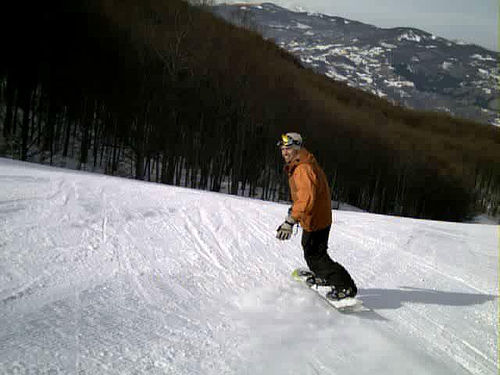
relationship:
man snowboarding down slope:
[274, 132, 356, 302] [68, 212, 245, 360]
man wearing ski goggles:
[274, 132, 356, 302] [275, 133, 302, 147]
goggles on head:
[275, 133, 302, 147] [274, 127, 305, 164]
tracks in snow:
[175, 267, 292, 329] [29, 177, 474, 364]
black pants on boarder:
[301, 223, 356, 292] [271, 128, 360, 302]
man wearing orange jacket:
[274, 132, 356, 302] [278, 149, 335, 234]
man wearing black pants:
[274, 132, 356, 302] [302, 221, 356, 291]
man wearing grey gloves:
[274, 132, 356, 302] [271, 211, 301, 245]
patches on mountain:
[0, 156, 465, 372] [9, 2, 490, 222]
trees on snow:
[0, 0, 484, 234] [2, 151, 484, 371]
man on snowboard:
[274, 132, 356, 302] [284, 261, 367, 317]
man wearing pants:
[241, 117, 386, 311] [276, 214, 367, 291]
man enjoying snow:
[274, 132, 356, 302] [2, 151, 484, 371]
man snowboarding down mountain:
[274, 132, 356, 302] [4, 4, 467, 369]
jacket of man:
[283, 146, 333, 233] [274, 132, 356, 302]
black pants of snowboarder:
[293, 200, 355, 305] [271, 125, 363, 315]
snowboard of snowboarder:
[298, 245, 382, 327] [269, 122, 359, 306]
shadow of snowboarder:
[351, 278, 484, 321] [264, 120, 371, 316]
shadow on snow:
[351, 278, 484, 321] [76, 239, 240, 326]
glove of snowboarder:
[275, 206, 294, 240] [261, 124, 377, 356]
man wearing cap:
[274, 132, 356, 302] [275, 130, 301, 149]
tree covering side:
[165, 55, 191, 182] [2, 1, 483, 220]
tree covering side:
[265, 68, 286, 195] [2, 1, 483, 220]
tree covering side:
[95, 34, 122, 168] [2, 1, 483, 220]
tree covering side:
[22, 18, 52, 150] [2, 1, 483, 220]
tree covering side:
[3, 1, 28, 159] [2, 1, 483, 220]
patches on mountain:
[275, 4, 445, 118] [204, 0, 484, 142]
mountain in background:
[204, 0, 484, 142] [164, 3, 482, 137]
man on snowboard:
[274, 132, 356, 302] [293, 265, 361, 317]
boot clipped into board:
[296, 267, 388, 312] [287, 257, 366, 316]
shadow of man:
[351, 285, 499, 321] [274, 132, 356, 302]